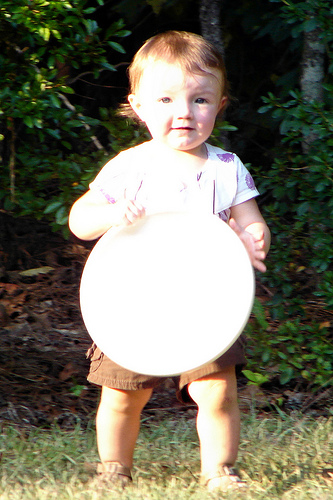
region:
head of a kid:
[117, 27, 252, 145]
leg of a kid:
[179, 372, 264, 499]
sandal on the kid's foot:
[202, 460, 257, 499]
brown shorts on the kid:
[77, 352, 146, 405]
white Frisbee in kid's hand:
[75, 210, 250, 359]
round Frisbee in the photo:
[60, 205, 275, 374]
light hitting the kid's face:
[131, 52, 191, 132]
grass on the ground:
[242, 433, 304, 495]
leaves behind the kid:
[275, 323, 324, 366]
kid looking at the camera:
[87, 35, 266, 201]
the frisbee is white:
[85, 203, 230, 398]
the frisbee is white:
[86, 218, 267, 428]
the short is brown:
[90, 347, 211, 406]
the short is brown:
[85, 321, 268, 432]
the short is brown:
[112, 364, 239, 433]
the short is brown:
[53, 321, 262, 423]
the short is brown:
[73, 323, 265, 405]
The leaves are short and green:
[23, 12, 64, 124]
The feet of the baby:
[84, 451, 260, 495]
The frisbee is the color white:
[76, 208, 257, 380]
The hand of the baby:
[107, 193, 148, 232]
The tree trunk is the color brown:
[299, 28, 329, 177]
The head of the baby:
[112, 25, 246, 153]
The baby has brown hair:
[104, 23, 245, 152]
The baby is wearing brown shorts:
[82, 314, 250, 406]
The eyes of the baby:
[155, 85, 217, 112]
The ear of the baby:
[126, 90, 151, 122]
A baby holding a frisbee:
[64, 31, 280, 496]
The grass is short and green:
[16, 437, 87, 496]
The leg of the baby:
[89, 371, 147, 461]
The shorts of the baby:
[72, 332, 274, 410]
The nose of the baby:
[172, 102, 195, 121]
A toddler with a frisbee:
[65, 30, 260, 496]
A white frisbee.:
[80, 208, 251, 378]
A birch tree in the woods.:
[284, 2, 331, 237]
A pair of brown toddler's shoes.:
[89, 454, 251, 493]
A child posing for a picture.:
[125, 29, 229, 153]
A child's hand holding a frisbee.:
[68, 141, 152, 240]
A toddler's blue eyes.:
[158, 93, 208, 109]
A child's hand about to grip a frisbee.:
[220, 205, 272, 290]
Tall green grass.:
[3, 404, 332, 498]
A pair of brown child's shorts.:
[81, 303, 247, 389]